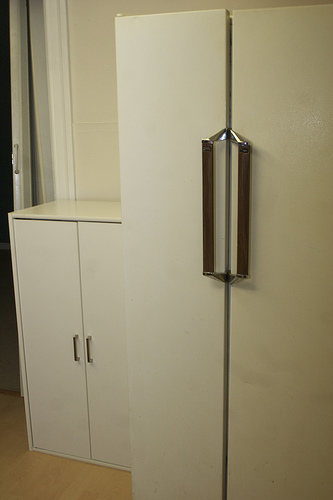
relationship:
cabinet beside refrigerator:
[5, 196, 139, 477] [113, 0, 330, 499]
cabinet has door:
[5, 196, 139, 477] [74, 216, 138, 477]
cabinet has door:
[5, 196, 139, 477] [10, 211, 96, 464]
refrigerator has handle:
[113, 0, 330, 499] [228, 125, 254, 287]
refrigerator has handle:
[113, 0, 330, 499] [199, 125, 231, 285]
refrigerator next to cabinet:
[113, 0, 330, 499] [5, 196, 139, 477]